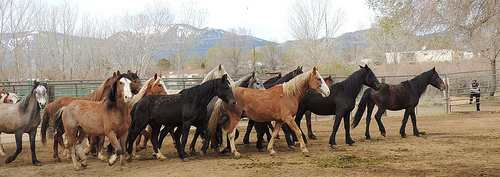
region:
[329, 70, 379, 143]
the horse is black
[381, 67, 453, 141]
the horse is brown and black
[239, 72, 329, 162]
the horse is brown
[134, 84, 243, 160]
the horse is black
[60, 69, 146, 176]
theb horse is brown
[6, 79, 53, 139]
the horse is white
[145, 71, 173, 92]
the horse is brown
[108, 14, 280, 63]
hill is in the background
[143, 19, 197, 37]
snow is on the hill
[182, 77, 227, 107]
the mane is black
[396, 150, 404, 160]
part of a ground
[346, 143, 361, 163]
part of a ground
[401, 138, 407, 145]
part iof a ground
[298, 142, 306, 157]
poart of a leg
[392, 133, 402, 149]
part of a gfround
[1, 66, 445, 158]
Horses walking in a ranch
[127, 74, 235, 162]
A black colored horse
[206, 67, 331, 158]
Brown horse with white mane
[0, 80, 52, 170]
A gray colored horse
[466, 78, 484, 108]
Person standing behind a fence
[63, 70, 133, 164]
Brown horse with black mane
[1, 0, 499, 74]
Bare trees behind the fence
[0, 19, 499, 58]
Mountains in the background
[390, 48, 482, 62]
White building in the background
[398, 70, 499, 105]
A fence made of metal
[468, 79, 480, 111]
person in the distance looking at horses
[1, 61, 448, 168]
group of horses walking on the field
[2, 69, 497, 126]
fence separating horses and humans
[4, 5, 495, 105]
dried up autumn trees in the background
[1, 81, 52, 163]
horse with grey hair on the neck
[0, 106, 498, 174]
grass for the horses to run and walk on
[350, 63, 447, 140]
horse at the front of the pack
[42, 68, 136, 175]
horse in a galloping mode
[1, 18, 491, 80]
cold snowy mountains in the distance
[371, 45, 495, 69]
house in the background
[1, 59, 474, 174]
a herd of horses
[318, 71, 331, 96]
thick white stripe on the face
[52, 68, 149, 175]
brown and white horse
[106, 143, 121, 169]
paw is lifted in the air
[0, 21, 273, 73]
mountains in the distance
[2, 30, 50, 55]
snow on the cliff side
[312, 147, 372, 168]
patch of green grass on the ground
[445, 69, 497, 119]
person standing on the other side of the fence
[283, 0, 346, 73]
tree with no leaves on it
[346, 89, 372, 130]
long dark hair on the tail